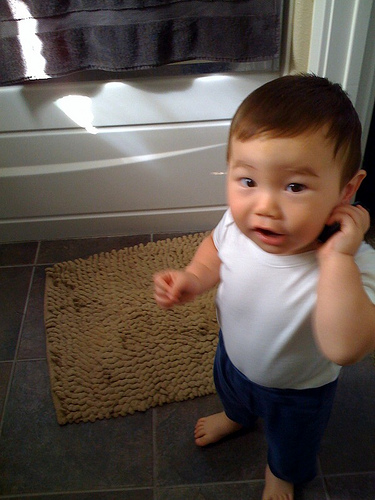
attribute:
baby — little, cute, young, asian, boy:
[155, 74, 368, 495]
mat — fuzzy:
[88, 270, 182, 395]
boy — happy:
[126, 61, 372, 419]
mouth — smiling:
[243, 217, 291, 255]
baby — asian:
[172, 90, 363, 483]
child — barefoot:
[151, 72, 374, 498]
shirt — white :
[210, 203, 372, 390]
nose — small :
[254, 196, 285, 221]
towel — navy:
[2, 2, 179, 77]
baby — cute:
[158, 68, 373, 328]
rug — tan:
[43, 229, 258, 424]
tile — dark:
[86, 434, 192, 483]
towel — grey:
[2, 3, 289, 79]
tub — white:
[3, 75, 287, 236]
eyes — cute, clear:
[223, 169, 316, 204]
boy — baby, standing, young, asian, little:
[152, 74, 373, 498]